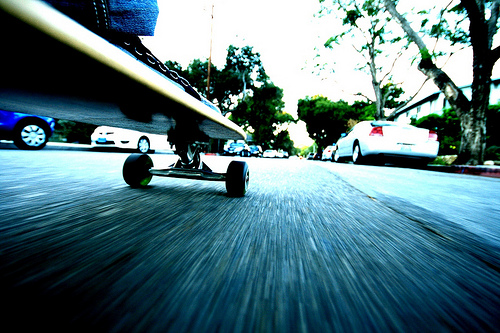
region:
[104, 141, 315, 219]
skating wheels are visible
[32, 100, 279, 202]
skating wheels are visible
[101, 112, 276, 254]
skating wheels are visible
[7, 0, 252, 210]
a skateboard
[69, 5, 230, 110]
black shoe on a skateboarder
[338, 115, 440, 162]
a silver sedan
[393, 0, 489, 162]
a tree on the sidewalk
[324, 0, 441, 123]
a tree on the sidewalk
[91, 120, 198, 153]
a white sedan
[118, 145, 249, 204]
the front wheels of the skateboard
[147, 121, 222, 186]
a truck of the skateboard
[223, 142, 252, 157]
a black sedan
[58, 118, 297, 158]
a line of parked cars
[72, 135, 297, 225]
the wheels are moving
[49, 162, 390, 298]
the street is grey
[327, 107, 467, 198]
the car is parked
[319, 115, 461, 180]
the car is white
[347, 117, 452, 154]
the brakes are red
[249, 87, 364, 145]
the trees are ahead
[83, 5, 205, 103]
the person is wearing socks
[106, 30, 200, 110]
the socks are black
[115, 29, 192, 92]
the socks have white circles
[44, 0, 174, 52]
the skateboarder is wearing jeans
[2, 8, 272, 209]
A foot on a skateboard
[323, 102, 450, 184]
A white car parked at the curb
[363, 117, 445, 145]
Red tail lights on car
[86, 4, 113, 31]
White seam of blue pants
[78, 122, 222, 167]
A white car traveling on the road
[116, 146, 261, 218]
Front two wheels of skateboard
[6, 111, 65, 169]
Part of a blue vehicle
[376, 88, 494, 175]
A white house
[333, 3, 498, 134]
Two trees by white car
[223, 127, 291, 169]
A row of parked cars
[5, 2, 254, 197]
the skateboard on the street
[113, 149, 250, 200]
the wheels of the skateboard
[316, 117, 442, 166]
cars parked on the side of the road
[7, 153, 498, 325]
the road the cars are parked on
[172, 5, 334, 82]
a patch of blue sky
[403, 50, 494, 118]
a big house off to the side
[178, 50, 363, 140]
some trees off to the side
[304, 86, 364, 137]
another green leafy tree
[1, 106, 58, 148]
a blue car parked off to the side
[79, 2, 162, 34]
some jeans the skater is wearing